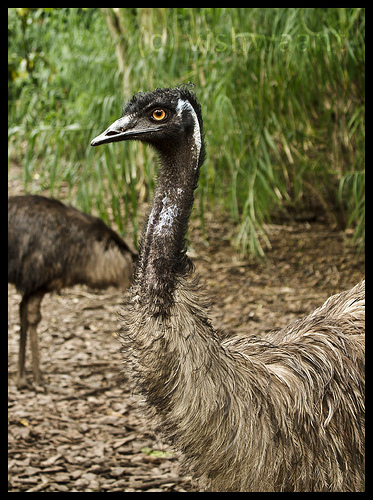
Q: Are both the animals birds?
A: Yes, all the animals are birds.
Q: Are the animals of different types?
A: No, all the animals are birds.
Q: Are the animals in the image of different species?
A: No, all the animals are birds.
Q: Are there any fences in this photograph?
A: No, there are no fences.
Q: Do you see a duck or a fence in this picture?
A: No, there are no fences or ducks.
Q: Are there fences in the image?
A: No, there are no fences.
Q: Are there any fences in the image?
A: No, there are no fences.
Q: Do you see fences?
A: No, there are no fences.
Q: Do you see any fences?
A: No, there are no fences.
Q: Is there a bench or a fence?
A: No, there are no fences or benches.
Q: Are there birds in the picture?
A: Yes, there is a bird.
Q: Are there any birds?
A: Yes, there is a bird.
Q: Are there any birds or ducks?
A: Yes, there is a bird.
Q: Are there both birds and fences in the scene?
A: No, there is a bird but no fences.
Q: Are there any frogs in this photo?
A: No, there are no frogs.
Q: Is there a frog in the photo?
A: No, there are no frogs.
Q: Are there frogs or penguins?
A: No, there are no frogs or penguins.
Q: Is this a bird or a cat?
A: This is a bird.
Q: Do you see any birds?
A: Yes, there is a bird.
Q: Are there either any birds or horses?
A: Yes, there is a bird.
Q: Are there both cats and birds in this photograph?
A: No, there is a bird but no cats.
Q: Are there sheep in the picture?
A: No, there are no sheep.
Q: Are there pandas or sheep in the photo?
A: No, there are no sheep or pandas.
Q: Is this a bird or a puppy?
A: This is a bird.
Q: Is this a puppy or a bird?
A: This is a bird.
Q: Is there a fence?
A: No, there are no fences.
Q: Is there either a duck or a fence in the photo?
A: No, there are no fences or ducks.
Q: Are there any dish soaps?
A: No, there are no dish soaps.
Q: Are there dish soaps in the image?
A: No, there are no dish soaps.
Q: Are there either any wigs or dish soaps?
A: No, there are no dish soaps or wigs.